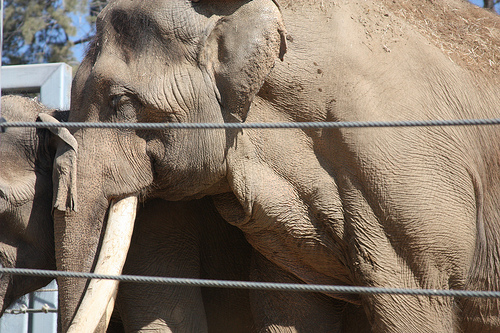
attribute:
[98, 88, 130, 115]
eyes — sad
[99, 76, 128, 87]
eyebrows — gray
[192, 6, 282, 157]
ear — large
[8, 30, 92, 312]
gate — metal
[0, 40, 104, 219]
door — metal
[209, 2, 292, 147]
ear — injured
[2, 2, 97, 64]
sky — clear, blue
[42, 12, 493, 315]
elephant — standing., large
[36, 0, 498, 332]
elephant — white, sleeping, grey, large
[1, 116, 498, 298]
fence — wire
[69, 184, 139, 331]
tusk — long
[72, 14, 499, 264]
elephant — smaller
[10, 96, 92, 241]
elephant — sad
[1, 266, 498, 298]
wire — retaining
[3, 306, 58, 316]
fence — barbed-wire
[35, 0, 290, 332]
elephant — brown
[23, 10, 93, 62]
trees — tall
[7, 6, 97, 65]
tree — green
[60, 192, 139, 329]
tusk — white, long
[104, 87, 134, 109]
eyes — closed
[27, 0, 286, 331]
elephant tusk — white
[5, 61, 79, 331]
gate — white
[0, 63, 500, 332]
pen — elephant pen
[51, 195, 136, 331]
tusk — long